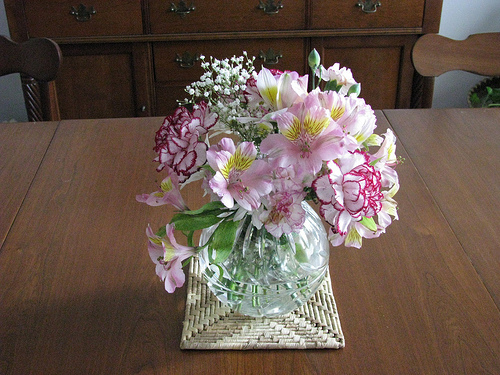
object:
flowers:
[259, 107, 346, 185]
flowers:
[372, 128, 398, 164]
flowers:
[200, 137, 276, 210]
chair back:
[0, 34, 62, 83]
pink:
[170, 263, 179, 281]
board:
[0, 108, 500, 372]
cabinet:
[3, 0, 442, 123]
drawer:
[21, 0, 143, 36]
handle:
[70, 7, 96, 21]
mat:
[179, 255, 347, 350]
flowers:
[176, 51, 281, 151]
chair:
[411, 32, 499, 76]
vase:
[198, 201, 330, 318]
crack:
[0, 120, 61, 247]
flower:
[152, 101, 219, 184]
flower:
[243, 69, 309, 110]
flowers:
[135, 172, 189, 211]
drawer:
[305, 0, 425, 29]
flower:
[311, 150, 384, 237]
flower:
[259, 189, 308, 241]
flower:
[146, 222, 197, 294]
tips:
[338, 160, 387, 209]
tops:
[412, 34, 464, 77]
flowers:
[308, 48, 321, 70]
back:
[412, 30, 500, 76]